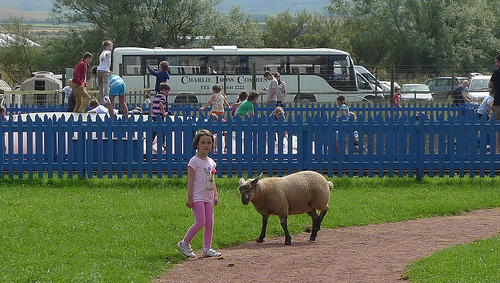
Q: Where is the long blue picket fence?
A: Behind the girl.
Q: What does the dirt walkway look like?
A: Brown dirt.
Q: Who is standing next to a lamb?
A: The girl.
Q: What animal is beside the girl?
A: Sheep.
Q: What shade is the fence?
A: Blue.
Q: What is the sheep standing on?
A: Path.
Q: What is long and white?
A: Bus.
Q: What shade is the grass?
A: Green.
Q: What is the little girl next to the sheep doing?
A: Standing.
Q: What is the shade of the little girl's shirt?
A: Pink.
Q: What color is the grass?
A: Green.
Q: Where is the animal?
A: In a park.